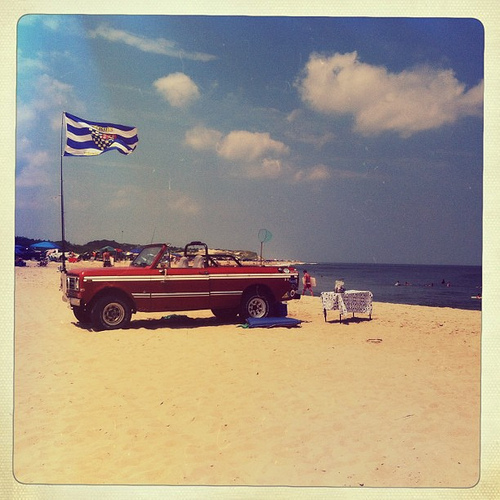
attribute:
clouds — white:
[158, 65, 215, 120]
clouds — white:
[209, 111, 345, 183]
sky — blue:
[22, 20, 467, 278]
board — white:
[300, 272, 319, 285]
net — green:
[256, 230, 271, 263]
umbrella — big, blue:
[27, 231, 63, 275]